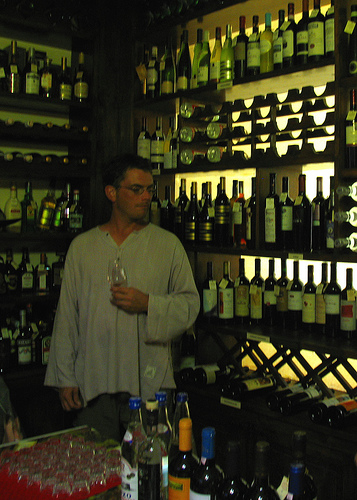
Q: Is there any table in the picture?
A: Yes, there is a table.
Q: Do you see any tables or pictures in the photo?
A: Yes, there is a table.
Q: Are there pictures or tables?
A: Yes, there is a table.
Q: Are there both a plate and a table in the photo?
A: No, there is a table but no plates.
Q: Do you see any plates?
A: No, there are no plates.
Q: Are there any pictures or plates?
A: No, there are no plates or pictures.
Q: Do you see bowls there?
A: No, there are no bowls.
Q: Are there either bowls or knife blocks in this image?
A: No, there are no bowls or knife blocks.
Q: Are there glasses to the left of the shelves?
A: Yes, there are glasses to the left of the shelves.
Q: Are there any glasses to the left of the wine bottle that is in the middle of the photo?
A: Yes, there are glasses to the left of the wine bottle.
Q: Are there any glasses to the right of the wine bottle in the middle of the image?
A: No, the glasses are to the left of the wine bottle.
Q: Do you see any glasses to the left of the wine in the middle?
A: Yes, there are glasses to the left of the wine.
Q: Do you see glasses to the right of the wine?
A: No, the glasses are to the left of the wine.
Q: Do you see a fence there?
A: No, there are no fences.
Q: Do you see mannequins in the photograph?
A: No, there are no mannequins.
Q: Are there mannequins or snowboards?
A: No, there are no mannequins or snowboards.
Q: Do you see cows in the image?
A: No, there are no cows.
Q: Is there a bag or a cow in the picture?
A: No, there are no cows or bags.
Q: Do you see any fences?
A: No, there are no fences.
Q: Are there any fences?
A: No, there are no fences.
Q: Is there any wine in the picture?
A: Yes, there is wine.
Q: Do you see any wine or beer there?
A: Yes, there is wine.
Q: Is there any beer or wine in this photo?
A: Yes, there is wine.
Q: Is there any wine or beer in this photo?
A: Yes, there is wine.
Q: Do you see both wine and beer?
A: No, there is wine but no beer.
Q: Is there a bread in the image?
A: No, there is no breads.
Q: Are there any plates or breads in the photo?
A: No, there are no breads or plates.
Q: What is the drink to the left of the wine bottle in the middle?
A: The drink is wine.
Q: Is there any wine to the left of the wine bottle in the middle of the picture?
A: Yes, there is wine to the left of the wine bottle.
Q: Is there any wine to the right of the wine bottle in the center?
A: No, the wine is to the left of the wine bottle.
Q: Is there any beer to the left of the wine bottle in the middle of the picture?
A: No, there is wine to the left of the wine bottle.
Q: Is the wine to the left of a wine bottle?
A: Yes, the wine is to the left of a wine bottle.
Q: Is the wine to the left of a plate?
A: No, the wine is to the left of a wine bottle.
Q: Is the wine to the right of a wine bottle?
A: No, the wine is to the left of a wine bottle.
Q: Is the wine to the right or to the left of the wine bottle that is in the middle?
A: The wine is to the left of the wine bottle.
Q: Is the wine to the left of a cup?
A: No, the wine is to the left of a wine bottle.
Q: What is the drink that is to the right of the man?
A: The drink is wine.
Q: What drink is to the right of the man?
A: The drink is wine.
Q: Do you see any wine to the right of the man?
A: Yes, there is wine to the right of the man.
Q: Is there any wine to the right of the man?
A: Yes, there is wine to the right of the man.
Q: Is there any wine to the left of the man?
A: No, the wine is to the right of the man.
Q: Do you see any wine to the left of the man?
A: No, the wine is to the right of the man.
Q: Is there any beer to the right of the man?
A: No, there is wine to the right of the man.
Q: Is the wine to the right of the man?
A: Yes, the wine is to the right of the man.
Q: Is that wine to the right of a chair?
A: No, the wine is to the right of the man.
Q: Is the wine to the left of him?
A: No, the wine is to the right of the man.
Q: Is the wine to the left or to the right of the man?
A: The wine is to the right of the man.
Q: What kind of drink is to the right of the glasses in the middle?
A: The drink is wine.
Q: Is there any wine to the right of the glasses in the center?
A: Yes, there is wine to the right of the glasses.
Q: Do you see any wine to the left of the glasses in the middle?
A: No, the wine is to the right of the glasses.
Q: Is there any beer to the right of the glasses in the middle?
A: No, there is wine to the right of the glasses.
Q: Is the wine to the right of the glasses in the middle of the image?
A: Yes, the wine is to the right of the glasses.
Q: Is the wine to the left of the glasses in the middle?
A: No, the wine is to the right of the glasses.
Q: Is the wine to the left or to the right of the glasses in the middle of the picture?
A: The wine is to the right of the glasses.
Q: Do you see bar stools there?
A: No, there are no bar stools.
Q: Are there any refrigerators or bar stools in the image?
A: No, there are no bar stools or refrigerators.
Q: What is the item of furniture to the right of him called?
A: The piece of furniture is a shelf.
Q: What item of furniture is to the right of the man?
A: The piece of furniture is a shelf.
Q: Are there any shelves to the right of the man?
A: Yes, there is a shelf to the right of the man.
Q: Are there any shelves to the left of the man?
A: No, the shelf is to the right of the man.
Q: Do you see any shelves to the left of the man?
A: No, the shelf is to the right of the man.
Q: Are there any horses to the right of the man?
A: No, there is a shelf to the right of the man.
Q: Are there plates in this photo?
A: No, there are no plates.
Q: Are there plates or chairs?
A: No, there are no plates or chairs.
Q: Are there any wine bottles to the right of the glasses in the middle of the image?
A: Yes, there is a wine bottle to the right of the glasses.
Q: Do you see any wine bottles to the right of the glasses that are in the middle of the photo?
A: Yes, there is a wine bottle to the right of the glasses.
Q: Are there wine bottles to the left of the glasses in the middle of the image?
A: No, the wine bottle is to the right of the glasses.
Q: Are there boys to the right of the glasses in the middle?
A: No, there is a wine bottle to the right of the glasses.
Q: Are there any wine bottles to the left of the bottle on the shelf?
A: Yes, there is a wine bottle to the left of the bottle.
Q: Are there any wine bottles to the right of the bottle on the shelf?
A: No, the wine bottle is to the left of the bottle.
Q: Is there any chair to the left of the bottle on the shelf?
A: No, there is a wine bottle to the left of the bottle.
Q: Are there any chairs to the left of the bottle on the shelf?
A: No, there is a wine bottle to the left of the bottle.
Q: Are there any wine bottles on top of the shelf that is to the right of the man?
A: Yes, there is a wine bottle on top of the shelf.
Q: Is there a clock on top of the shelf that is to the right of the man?
A: No, there is a wine bottle on top of the shelf.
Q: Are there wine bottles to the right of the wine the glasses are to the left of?
A: Yes, there is a wine bottle to the right of the wine.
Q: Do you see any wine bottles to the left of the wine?
A: No, the wine bottle is to the right of the wine.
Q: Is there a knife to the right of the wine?
A: No, there is a wine bottle to the right of the wine.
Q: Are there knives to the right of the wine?
A: No, there is a wine bottle to the right of the wine.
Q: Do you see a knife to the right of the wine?
A: No, there is a wine bottle to the right of the wine.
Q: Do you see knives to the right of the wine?
A: No, there is a wine bottle to the right of the wine.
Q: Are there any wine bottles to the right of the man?
A: Yes, there is a wine bottle to the right of the man.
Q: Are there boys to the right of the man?
A: No, there is a wine bottle to the right of the man.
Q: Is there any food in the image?
A: No, there is no food.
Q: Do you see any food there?
A: No, there is no food.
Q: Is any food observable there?
A: No, there is no food.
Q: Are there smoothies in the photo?
A: No, there are no smoothies.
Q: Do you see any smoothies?
A: No, there are no smoothies.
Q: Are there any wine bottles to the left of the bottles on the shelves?
A: Yes, there is a wine bottle to the left of the bottles.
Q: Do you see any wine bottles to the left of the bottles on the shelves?
A: Yes, there is a wine bottle to the left of the bottles.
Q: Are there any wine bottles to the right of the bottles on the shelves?
A: No, the wine bottle is to the left of the bottles.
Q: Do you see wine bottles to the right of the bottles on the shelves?
A: No, the wine bottle is to the left of the bottles.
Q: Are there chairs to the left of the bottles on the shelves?
A: No, there is a wine bottle to the left of the bottles.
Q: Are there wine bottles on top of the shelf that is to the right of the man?
A: Yes, there is a wine bottle on top of the shelf.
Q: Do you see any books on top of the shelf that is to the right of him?
A: No, there is a wine bottle on top of the shelf.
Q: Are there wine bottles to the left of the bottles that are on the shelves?
A: Yes, there is a wine bottle to the left of the bottles.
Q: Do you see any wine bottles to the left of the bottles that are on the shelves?
A: Yes, there is a wine bottle to the left of the bottles.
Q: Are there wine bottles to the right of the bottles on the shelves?
A: No, the wine bottle is to the left of the bottles.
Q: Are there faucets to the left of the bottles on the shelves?
A: No, there is a wine bottle to the left of the bottles.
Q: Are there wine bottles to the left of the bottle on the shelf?
A: Yes, there is a wine bottle to the left of the bottle.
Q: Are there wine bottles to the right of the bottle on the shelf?
A: No, the wine bottle is to the left of the bottle.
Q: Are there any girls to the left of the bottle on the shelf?
A: No, there is a wine bottle to the left of the bottle.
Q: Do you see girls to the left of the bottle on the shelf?
A: No, there is a wine bottle to the left of the bottle.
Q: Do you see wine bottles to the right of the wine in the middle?
A: Yes, there is a wine bottle to the right of the wine.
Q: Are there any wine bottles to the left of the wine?
A: No, the wine bottle is to the right of the wine.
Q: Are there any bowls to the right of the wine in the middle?
A: No, there is a wine bottle to the right of the wine.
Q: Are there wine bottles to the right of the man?
A: Yes, there is a wine bottle to the right of the man.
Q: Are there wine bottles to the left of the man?
A: No, the wine bottle is to the right of the man.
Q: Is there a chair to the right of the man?
A: No, there is a wine bottle to the right of the man.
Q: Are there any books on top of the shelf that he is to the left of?
A: No, there is a wine bottle on top of the shelf.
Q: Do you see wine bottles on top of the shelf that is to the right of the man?
A: Yes, there is a wine bottle on top of the shelf.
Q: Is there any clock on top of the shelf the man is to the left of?
A: No, there is a wine bottle on top of the shelf.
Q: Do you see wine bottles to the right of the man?
A: Yes, there is a wine bottle to the right of the man.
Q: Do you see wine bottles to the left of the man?
A: No, the wine bottle is to the right of the man.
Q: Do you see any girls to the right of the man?
A: No, there is a wine bottle to the right of the man.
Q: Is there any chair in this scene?
A: No, there are no chairs.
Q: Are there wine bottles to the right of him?
A: Yes, there is a wine bottle to the right of the man.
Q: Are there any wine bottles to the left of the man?
A: No, the wine bottle is to the right of the man.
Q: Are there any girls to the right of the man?
A: No, there is a wine bottle to the right of the man.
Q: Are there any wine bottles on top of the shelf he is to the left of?
A: Yes, there is a wine bottle on top of the shelf.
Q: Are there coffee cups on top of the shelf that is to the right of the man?
A: No, there is a wine bottle on top of the shelf.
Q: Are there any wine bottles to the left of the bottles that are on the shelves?
A: Yes, there is a wine bottle to the left of the bottles.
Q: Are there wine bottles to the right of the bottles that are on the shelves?
A: No, the wine bottle is to the left of the bottles.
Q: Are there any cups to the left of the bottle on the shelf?
A: No, there is a wine bottle to the left of the bottle.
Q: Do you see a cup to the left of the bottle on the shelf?
A: No, there is a wine bottle to the left of the bottle.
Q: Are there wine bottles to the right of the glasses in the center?
A: Yes, there is a wine bottle to the right of the glasses.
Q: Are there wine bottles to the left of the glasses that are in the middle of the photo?
A: No, the wine bottle is to the right of the glasses.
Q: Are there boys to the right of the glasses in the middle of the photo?
A: No, there is a wine bottle to the right of the glasses.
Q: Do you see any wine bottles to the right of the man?
A: Yes, there is a wine bottle to the right of the man.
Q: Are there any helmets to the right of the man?
A: No, there is a wine bottle to the right of the man.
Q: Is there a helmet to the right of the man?
A: No, there is a wine bottle to the right of the man.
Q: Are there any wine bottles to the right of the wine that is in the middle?
A: Yes, there is a wine bottle to the right of the wine.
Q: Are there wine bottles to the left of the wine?
A: No, the wine bottle is to the right of the wine.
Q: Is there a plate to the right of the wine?
A: No, there is a wine bottle to the right of the wine.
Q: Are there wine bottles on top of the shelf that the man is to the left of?
A: Yes, there is a wine bottle on top of the shelf.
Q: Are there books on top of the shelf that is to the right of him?
A: No, there is a wine bottle on top of the shelf.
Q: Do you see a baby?
A: No, there are no babies.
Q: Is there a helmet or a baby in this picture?
A: No, there are no babies or helmets.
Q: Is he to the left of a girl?
A: No, the man is to the left of a wine bottle.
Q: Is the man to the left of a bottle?
A: Yes, the man is to the left of a bottle.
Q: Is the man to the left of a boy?
A: No, the man is to the left of a bottle.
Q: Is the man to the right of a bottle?
A: No, the man is to the left of a bottle.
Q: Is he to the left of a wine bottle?
A: Yes, the man is to the left of a wine bottle.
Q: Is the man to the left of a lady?
A: No, the man is to the left of a wine bottle.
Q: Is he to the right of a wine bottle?
A: No, the man is to the left of a wine bottle.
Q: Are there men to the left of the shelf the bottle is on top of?
A: Yes, there is a man to the left of the shelf.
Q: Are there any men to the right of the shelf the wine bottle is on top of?
A: No, the man is to the left of the shelf.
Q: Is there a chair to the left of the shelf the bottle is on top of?
A: No, there is a man to the left of the shelf.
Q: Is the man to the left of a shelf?
A: Yes, the man is to the left of a shelf.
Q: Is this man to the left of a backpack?
A: No, the man is to the left of a shelf.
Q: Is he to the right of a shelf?
A: No, the man is to the left of a shelf.